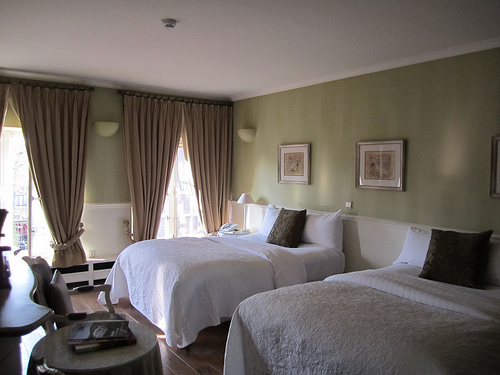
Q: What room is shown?
A: It is a bedroom.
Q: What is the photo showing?
A: It is showing a bedroom.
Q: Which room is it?
A: It is a bedroom.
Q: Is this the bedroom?
A: Yes, it is the bedroom.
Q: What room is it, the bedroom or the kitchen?
A: It is the bedroom.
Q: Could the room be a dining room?
A: No, it is a bedroom.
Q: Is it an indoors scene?
A: Yes, it is indoors.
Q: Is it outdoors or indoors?
A: It is indoors.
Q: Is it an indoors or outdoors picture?
A: It is indoors.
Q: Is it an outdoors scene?
A: No, it is indoors.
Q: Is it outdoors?
A: No, it is indoors.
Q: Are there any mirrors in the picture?
A: No, there are no mirrors.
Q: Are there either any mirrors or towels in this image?
A: No, there are no mirrors or towels.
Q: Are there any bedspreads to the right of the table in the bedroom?
A: Yes, there is a bedspread to the right of the table.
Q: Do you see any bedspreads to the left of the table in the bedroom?
A: No, the bedspread is to the right of the table.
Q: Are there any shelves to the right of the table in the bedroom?
A: No, there is a bedspread to the right of the table.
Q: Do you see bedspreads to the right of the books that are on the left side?
A: Yes, there is a bedspread to the right of the books.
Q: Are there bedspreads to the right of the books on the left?
A: Yes, there is a bedspread to the right of the books.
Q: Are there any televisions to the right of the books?
A: No, there is a bedspread to the right of the books.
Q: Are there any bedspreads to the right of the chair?
A: Yes, there is a bedspread to the right of the chair.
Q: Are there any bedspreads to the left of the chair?
A: No, the bedspread is to the right of the chair.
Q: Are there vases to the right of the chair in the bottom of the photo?
A: No, there is a bedspread to the right of the chair.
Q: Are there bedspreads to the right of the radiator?
A: Yes, there is a bedspread to the right of the radiator.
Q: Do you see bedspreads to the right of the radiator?
A: Yes, there is a bedspread to the right of the radiator.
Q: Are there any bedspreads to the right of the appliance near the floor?
A: Yes, there is a bedspread to the right of the radiator.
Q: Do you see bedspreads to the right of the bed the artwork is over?
A: Yes, there is a bedspread to the right of the bed.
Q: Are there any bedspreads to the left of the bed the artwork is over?
A: No, the bedspread is to the right of the bed.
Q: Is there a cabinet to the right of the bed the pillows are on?
A: No, there is a bedspread to the right of the bed.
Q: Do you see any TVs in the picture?
A: No, there are no tvs.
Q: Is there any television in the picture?
A: No, there are no televisions.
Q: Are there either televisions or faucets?
A: No, there are no televisions or faucets.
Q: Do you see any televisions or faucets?
A: No, there are no televisions or faucets.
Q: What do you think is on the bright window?
A: The curtain is on the window.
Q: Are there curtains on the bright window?
A: Yes, there is a curtain on the window.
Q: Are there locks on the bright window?
A: No, there is a curtain on the window.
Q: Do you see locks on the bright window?
A: No, there is a curtain on the window.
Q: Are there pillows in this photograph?
A: Yes, there are pillows.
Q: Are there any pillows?
A: Yes, there are pillows.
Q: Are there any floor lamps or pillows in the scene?
A: Yes, there are pillows.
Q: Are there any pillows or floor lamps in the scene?
A: Yes, there are pillows.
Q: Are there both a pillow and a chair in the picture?
A: Yes, there are both a pillow and a chair.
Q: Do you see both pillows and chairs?
A: Yes, there are both pillows and a chair.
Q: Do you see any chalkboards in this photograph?
A: No, there are no chalkboards.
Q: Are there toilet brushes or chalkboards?
A: No, there are no chalkboards or toilet brushes.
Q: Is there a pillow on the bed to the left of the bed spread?
A: Yes, there are pillows on the bed.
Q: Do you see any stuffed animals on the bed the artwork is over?
A: No, there are pillows on the bed.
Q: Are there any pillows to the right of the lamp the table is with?
A: Yes, there are pillows to the right of the lamp.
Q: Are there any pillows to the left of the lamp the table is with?
A: No, the pillows are to the right of the lamp.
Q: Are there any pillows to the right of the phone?
A: Yes, there are pillows to the right of the phone.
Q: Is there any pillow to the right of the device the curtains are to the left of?
A: Yes, there are pillows to the right of the phone.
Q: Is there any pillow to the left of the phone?
A: No, the pillows are to the right of the phone.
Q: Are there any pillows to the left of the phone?
A: No, the pillows are to the right of the phone.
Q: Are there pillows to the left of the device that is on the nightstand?
A: No, the pillows are to the right of the phone.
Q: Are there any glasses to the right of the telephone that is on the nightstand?
A: No, there are pillows to the right of the phone.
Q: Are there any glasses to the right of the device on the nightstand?
A: No, there are pillows to the right of the phone.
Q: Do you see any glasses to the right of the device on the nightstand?
A: No, there are pillows to the right of the phone.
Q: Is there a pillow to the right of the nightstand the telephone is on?
A: Yes, there are pillows to the right of the nightstand.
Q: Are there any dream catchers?
A: No, there are no dream catchers.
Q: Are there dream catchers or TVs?
A: No, there are no dream catchers or tvs.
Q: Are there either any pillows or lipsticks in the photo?
A: Yes, there is a pillow.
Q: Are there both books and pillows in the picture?
A: Yes, there are both a pillow and a book.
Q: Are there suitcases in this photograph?
A: No, there are no suitcases.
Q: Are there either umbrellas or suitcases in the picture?
A: No, there are no suitcases or umbrellas.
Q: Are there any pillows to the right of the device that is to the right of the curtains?
A: Yes, there is a pillow to the right of the phone.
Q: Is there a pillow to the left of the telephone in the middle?
A: No, the pillow is to the right of the telephone.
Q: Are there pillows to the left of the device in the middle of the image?
A: No, the pillow is to the right of the telephone.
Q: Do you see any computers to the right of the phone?
A: No, there is a pillow to the right of the phone.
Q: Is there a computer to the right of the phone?
A: No, there is a pillow to the right of the phone.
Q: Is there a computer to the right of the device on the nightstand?
A: No, there is a pillow to the right of the phone.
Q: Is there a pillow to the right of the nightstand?
A: Yes, there is a pillow to the right of the nightstand.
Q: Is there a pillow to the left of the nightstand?
A: No, the pillow is to the right of the nightstand.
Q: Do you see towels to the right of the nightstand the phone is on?
A: No, there is a pillow to the right of the nightstand.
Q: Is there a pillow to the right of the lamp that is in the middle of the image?
A: Yes, there is a pillow to the right of the lamp.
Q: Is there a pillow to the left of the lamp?
A: No, the pillow is to the right of the lamp.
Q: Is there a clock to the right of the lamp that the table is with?
A: No, there is a pillow to the right of the lamp.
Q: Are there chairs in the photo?
A: Yes, there is a chair.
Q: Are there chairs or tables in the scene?
A: Yes, there is a chair.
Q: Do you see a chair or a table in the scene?
A: Yes, there is a chair.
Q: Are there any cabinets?
A: No, there are no cabinets.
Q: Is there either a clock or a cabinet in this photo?
A: No, there are no cabinets or clocks.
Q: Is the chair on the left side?
A: Yes, the chair is on the left of the image.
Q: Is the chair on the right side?
A: No, the chair is on the left of the image.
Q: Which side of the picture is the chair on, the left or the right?
A: The chair is on the left of the image.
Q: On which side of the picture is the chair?
A: The chair is on the left of the image.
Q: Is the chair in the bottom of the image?
A: Yes, the chair is in the bottom of the image.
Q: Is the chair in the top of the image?
A: No, the chair is in the bottom of the image.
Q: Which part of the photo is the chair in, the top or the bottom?
A: The chair is in the bottom of the image.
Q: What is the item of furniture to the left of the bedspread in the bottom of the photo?
A: The piece of furniture is a chair.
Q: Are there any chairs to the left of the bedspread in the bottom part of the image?
A: Yes, there is a chair to the left of the bed spread.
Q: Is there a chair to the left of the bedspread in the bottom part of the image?
A: Yes, there is a chair to the left of the bed spread.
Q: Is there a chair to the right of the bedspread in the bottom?
A: No, the chair is to the left of the bedspread.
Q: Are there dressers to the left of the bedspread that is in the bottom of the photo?
A: No, there is a chair to the left of the bed spread.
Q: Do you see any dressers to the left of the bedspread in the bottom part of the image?
A: No, there is a chair to the left of the bed spread.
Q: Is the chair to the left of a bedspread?
A: Yes, the chair is to the left of a bedspread.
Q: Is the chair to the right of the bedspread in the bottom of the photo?
A: No, the chair is to the left of the bedspread.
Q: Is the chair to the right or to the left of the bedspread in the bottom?
A: The chair is to the left of the bedspread.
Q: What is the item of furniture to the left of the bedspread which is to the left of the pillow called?
A: The piece of furniture is a chair.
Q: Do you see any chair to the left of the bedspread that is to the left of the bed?
A: Yes, there is a chair to the left of the bed spread.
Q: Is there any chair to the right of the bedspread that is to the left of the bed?
A: No, the chair is to the left of the bedspread.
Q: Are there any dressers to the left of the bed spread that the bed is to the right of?
A: No, there is a chair to the left of the bedspread.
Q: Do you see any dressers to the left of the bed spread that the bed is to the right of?
A: No, there is a chair to the left of the bedspread.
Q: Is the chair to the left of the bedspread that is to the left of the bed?
A: Yes, the chair is to the left of the bed spread.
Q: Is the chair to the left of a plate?
A: No, the chair is to the left of the bed spread.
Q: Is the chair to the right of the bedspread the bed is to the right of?
A: No, the chair is to the left of the bedspread.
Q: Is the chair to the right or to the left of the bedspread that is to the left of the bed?
A: The chair is to the left of the bedspread.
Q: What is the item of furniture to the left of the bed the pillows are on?
A: The piece of furniture is a chair.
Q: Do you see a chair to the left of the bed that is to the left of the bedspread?
A: Yes, there is a chair to the left of the bed.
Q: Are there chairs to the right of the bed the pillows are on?
A: No, the chair is to the left of the bed.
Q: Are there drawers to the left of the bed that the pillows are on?
A: No, there is a chair to the left of the bed.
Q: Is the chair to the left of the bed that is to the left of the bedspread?
A: Yes, the chair is to the left of the bed.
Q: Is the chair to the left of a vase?
A: No, the chair is to the left of the bed.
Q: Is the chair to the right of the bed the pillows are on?
A: No, the chair is to the left of the bed.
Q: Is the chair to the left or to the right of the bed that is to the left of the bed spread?
A: The chair is to the left of the bed.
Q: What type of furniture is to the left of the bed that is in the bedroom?
A: The piece of furniture is a chair.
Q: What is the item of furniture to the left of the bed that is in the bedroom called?
A: The piece of furniture is a chair.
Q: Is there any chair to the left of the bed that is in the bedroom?
A: Yes, there is a chair to the left of the bed.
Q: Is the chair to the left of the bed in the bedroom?
A: Yes, the chair is to the left of the bed.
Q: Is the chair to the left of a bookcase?
A: No, the chair is to the left of the bed.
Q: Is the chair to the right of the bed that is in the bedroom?
A: No, the chair is to the left of the bed.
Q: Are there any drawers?
A: No, there are no drawers.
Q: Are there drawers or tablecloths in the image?
A: No, there are no drawers or tablecloths.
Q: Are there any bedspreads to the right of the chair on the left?
A: Yes, there is a bedspread to the right of the chair.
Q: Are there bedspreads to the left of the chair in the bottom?
A: No, the bedspread is to the right of the chair.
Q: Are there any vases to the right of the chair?
A: No, there is a bedspread to the right of the chair.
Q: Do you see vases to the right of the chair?
A: No, there is a bedspread to the right of the chair.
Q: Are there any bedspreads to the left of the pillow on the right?
A: Yes, there is a bedspread to the left of the pillow.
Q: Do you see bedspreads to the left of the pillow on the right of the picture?
A: Yes, there is a bedspread to the left of the pillow.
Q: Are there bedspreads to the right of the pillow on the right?
A: No, the bedspread is to the left of the pillow.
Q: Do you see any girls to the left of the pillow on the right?
A: No, there is a bedspread to the left of the pillow.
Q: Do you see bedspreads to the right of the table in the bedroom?
A: Yes, there is a bedspread to the right of the table.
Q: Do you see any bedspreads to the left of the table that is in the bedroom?
A: No, the bedspread is to the right of the table.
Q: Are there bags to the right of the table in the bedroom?
A: No, there is a bedspread to the right of the table.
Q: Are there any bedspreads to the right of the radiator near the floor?
A: Yes, there is a bedspread to the right of the radiator.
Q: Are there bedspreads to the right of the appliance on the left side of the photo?
A: Yes, there is a bedspread to the right of the radiator.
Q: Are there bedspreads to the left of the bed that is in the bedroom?
A: Yes, there is a bedspread to the left of the bed.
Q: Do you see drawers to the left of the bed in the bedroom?
A: No, there is a bedspread to the left of the bed.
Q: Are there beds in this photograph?
A: Yes, there is a bed.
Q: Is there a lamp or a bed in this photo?
A: Yes, there is a bed.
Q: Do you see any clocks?
A: No, there are no clocks.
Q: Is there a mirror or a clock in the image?
A: No, there are no clocks or mirrors.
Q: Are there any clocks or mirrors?
A: No, there are no clocks or mirrors.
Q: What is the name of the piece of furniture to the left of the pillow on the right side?
A: The piece of furniture is a bed.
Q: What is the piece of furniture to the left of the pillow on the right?
A: The piece of furniture is a bed.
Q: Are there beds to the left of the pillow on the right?
A: Yes, there is a bed to the left of the pillow.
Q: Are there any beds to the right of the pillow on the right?
A: No, the bed is to the left of the pillow.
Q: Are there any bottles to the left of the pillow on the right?
A: No, there is a bed to the left of the pillow.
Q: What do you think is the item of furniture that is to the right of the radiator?
A: The piece of furniture is a bed.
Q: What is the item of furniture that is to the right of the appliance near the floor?
A: The piece of furniture is a bed.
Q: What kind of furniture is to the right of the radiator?
A: The piece of furniture is a bed.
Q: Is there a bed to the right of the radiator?
A: Yes, there is a bed to the right of the radiator.